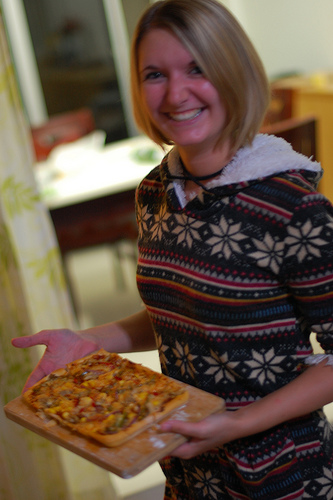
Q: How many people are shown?
A: One.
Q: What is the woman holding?
A: A cutting board.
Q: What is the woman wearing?
A: A sweater.